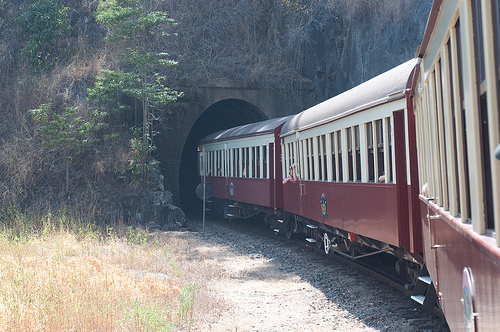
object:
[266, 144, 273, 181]
windows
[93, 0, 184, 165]
trees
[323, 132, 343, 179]
window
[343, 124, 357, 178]
window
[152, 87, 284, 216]
archway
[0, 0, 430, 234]
mountain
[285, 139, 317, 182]
windows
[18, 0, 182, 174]
foliage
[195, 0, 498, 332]
car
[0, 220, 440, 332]
ground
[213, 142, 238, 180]
windows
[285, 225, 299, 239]
wheel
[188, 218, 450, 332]
shade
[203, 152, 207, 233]
pole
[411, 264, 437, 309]
steps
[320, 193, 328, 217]
sign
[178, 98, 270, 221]
train tunnel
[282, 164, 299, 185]
people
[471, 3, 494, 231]
window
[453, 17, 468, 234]
window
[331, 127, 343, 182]
window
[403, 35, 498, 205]
windows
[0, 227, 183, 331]
dead grass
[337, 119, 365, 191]
windows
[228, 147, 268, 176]
windows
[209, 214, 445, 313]
track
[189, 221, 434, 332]
gravel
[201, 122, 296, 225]
train car